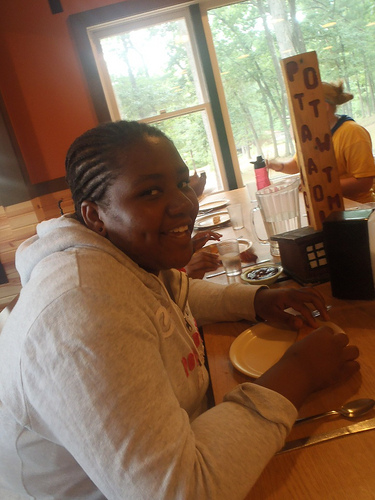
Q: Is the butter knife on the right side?
A: Yes, the butter knife is on the right of the image.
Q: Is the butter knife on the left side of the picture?
A: No, the butter knife is on the right of the image.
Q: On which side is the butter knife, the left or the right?
A: The butter knife is on the right of the image.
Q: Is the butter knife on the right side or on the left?
A: The butter knife is on the right of the image.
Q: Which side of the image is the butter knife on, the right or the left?
A: The butter knife is on the right of the image.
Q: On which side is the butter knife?
A: The butter knife is on the right of the image.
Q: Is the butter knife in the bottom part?
A: Yes, the butter knife is in the bottom of the image.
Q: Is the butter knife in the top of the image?
A: No, the butter knife is in the bottom of the image.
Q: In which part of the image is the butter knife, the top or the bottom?
A: The butter knife is in the bottom of the image.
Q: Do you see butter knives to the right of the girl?
A: Yes, there is a butter knife to the right of the girl.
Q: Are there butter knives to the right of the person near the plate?
A: Yes, there is a butter knife to the right of the girl.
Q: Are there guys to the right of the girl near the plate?
A: No, there is a butter knife to the right of the girl.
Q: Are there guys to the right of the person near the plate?
A: No, there is a butter knife to the right of the girl.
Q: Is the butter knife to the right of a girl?
A: Yes, the butter knife is to the right of a girl.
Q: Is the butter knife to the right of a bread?
A: No, the butter knife is to the right of a girl.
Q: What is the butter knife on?
A: The butter knife is on the table.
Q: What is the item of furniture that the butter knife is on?
A: The piece of furniture is a table.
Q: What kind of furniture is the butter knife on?
A: The butter knife is on the table.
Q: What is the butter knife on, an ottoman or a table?
A: The butter knife is on a table.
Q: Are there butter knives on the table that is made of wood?
A: Yes, there is a butter knife on the table.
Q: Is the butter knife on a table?
A: Yes, the butter knife is on a table.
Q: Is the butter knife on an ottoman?
A: No, the butter knife is on a table.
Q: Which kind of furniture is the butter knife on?
A: The butter knife is on the table.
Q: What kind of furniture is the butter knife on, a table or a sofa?
A: The butter knife is on a table.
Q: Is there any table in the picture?
A: Yes, there is a table.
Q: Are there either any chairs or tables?
A: Yes, there is a table.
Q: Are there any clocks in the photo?
A: No, there are no clocks.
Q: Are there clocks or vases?
A: No, there are no clocks or vases.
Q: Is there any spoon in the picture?
A: Yes, there is a spoon.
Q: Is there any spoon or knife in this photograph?
A: Yes, there is a spoon.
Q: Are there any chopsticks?
A: No, there are no chopsticks.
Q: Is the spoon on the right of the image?
A: Yes, the spoon is on the right of the image.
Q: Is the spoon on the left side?
A: No, the spoon is on the right of the image.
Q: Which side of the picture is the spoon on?
A: The spoon is on the right of the image.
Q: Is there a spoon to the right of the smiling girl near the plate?
A: Yes, there is a spoon to the right of the girl.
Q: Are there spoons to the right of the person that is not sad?
A: Yes, there is a spoon to the right of the girl.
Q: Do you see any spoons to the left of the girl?
A: No, the spoon is to the right of the girl.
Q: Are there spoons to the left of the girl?
A: No, the spoon is to the right of the girl.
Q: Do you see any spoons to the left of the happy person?
A: No, the spoon is to the right of the girl.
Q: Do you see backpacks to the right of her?
A: No, there is a spoon to the right of the girl.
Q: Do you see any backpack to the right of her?
A: No, there is a spoon to the right of the girl.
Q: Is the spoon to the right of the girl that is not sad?
A: Yes, the spoon is to the right of the girl.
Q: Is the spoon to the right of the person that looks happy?
A: Yes, the spoon is to the right of the girl.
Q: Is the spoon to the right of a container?
A: No, the spoon is to the right of the girl.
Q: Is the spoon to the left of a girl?
A: No, the spoon is to the right of a girl.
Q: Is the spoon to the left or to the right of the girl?
A: The spoon is to the right of the girl.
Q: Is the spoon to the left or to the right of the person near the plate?
A: The spoon is to the right of the girl.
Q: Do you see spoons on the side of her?
A: Yes, there is a spoon on the side of the girl.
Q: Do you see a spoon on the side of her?
A: Yes, there is a spoon on the side of the girl.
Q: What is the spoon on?
A: The spoon is on the table.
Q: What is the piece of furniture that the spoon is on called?
A: The piece of furniture is a table.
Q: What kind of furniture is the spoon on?
A: The spoon is on the table.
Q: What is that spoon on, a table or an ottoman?
A: The spoon is on a table.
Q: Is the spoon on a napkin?
A: No, the spoon is on a table.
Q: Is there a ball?
A: No, there are no balls.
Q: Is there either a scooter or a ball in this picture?
A: No, there are no balls or scooters.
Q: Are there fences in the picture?
A: No, there are no fences.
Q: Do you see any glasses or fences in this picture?
A: No, there are no fences or glasses.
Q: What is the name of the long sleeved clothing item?
A: The clothing item is a shirt.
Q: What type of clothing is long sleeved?
A: The clothing is a shirt.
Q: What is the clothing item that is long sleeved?
A: The clothing item is a shirt.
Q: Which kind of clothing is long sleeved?
A: The clothing is a shirt.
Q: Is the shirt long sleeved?
A: Yes, the shirt is long sleeved.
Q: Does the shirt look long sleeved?
A: Yes, the shirt is long sleeved.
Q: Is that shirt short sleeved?
A: No, the shirt is long sleeved.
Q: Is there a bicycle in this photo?
A: No, there are no bicycles.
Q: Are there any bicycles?
A: No, there are no bicycles.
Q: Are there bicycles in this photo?
A: No, there are no bicycles.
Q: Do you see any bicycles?
A: No, there are no bicycles.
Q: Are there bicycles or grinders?
A: No, there are no bicycles or grinders.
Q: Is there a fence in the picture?
A: No, there are no fences.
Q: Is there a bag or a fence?
A: No, there are no fences or bags.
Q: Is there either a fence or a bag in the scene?
A: No, there are no fences or bags.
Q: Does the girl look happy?
A: Yes, the girl is happy.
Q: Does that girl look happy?
A: Yes, the girl is happy.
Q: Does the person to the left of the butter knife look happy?
A: Yes, the girl is happy.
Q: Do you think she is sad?
A: No, the girl is happy.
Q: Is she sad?
A: No, the girl is happy.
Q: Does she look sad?
A: No, the girl is happy.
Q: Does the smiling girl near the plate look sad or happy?
A: The girl is happy.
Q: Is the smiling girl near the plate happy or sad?
A: The girl is happy.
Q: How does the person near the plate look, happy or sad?
A: The girl is happy.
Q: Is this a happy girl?
A: Yes, this is a happy girl.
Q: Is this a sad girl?
A: No, this is a happy girl.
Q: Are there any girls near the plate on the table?
A: Yes, there is a girl near the plate.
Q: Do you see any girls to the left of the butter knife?
A: Yes, there is a girl to the left of the butter knife.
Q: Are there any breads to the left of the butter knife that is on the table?
A: No, there is a girl to the left of the butter knife.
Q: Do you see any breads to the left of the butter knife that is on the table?
A: No, there is a girl to the left of the butter knife.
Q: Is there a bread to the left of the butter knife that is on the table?
A: No, there is a girl to the left of the butter knife.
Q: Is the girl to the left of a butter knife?
A: Yes, the girl is to the left of a butter knife.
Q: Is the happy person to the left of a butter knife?
A: Yes, the girl is to the left of a butter knife.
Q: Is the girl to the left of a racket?
A: No, the girl is to the left of a butter knife.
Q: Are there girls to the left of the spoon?
A: Yes, there is a girl to the left of the spoon.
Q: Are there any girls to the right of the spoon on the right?
A: No, the girl is to the left of the spoon.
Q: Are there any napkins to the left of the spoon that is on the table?
A: No, there is a girl to the left of the spoon.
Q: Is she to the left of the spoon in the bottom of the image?
A: Yes, the girl is to the left of the spoon.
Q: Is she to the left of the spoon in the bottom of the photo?
A: Yes, the girl is to the left of the spoon.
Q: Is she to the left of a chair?
A: No, the girl is to the left of the spoon.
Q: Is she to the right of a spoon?
A: No, the girl is to the left of a spoon.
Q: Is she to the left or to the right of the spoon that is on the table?
A: The girl is to the left of the spoon.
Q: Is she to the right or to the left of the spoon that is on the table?
A: The girl is to the left of the spoon.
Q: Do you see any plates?
A: Yes, there is a plate.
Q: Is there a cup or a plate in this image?
A: Yes, there is a plate.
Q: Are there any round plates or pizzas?
A: Yes, there is a round plate.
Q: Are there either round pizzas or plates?
A: Yes, there is a round plate.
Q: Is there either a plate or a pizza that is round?
A: Yes, the plate is round.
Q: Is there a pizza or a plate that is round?
A: Yes, the plate is round.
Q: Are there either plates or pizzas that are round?
A: Yes, the plate is round.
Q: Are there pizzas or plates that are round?
A: Yes, the plate is round.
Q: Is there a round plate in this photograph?
A: Yes, there is a round plate.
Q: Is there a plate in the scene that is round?
A: Yes, there is a plate that is round.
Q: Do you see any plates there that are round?
A: Yes, there is a plate that is round.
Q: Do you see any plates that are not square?
A: Yes, there is a round plate.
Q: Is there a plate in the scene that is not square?
A: Yes, there is a round plate.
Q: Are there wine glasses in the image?
A: No, there are no wine glasses.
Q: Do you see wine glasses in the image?
A: No, there are no wine glasses.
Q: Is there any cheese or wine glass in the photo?
A: No, there are no wine glasses or cheese.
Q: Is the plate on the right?
A: Yes, the plate is on the right of the image.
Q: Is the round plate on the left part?
A: No, the plate is on the right of the image.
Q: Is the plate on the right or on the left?
A: The plate is on the right of the image.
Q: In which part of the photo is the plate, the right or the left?
A: The plate is on the right of the image.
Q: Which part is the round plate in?
A: The plate is on the right of the image.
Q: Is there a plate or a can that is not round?
A: No, there is a plate but it is round.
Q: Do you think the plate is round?
A: Yes, the plate is round.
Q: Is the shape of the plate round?
A: Yes, the plate is round.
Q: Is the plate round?
A: Yes, the plate is round.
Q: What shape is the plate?
A: The plate is round.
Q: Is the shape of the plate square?
A: No, the plate is round.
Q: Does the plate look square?
A: No, the plate is round.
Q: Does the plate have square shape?
A: No, the plate is round.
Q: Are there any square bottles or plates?
A: No, there is a plate but it is round.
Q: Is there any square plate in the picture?
A: No, there is a plate but it is round.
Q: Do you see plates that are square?
A: No, there is a plate but it is round.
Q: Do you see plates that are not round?
A: No, there is a plate but it is round.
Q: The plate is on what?
A: The plate is on the table.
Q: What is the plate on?
A: The plate is on the table.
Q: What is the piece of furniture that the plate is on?
A: The piece of furniture is a table.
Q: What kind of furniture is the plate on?
A: The plate is on the table.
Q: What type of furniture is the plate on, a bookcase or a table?
A: The plate is on a table.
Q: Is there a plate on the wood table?
A: Yes, there is a plate on the table.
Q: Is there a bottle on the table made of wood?
A: No, there is a plate on the table.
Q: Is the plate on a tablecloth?
A: No, the plate is on the table.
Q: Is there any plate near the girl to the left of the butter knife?
A: Yes, there is a plate near the girl.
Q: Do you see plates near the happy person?
A: Yes, there is a plate near the girl.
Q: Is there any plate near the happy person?
A: Yes, there is a plate near the girl.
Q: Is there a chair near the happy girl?
A: No, there is a plate near the girl.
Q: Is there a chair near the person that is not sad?
A: No, there is a plate near the girl.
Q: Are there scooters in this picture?
A: No, there are no scooters.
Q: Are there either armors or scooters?
A: No, there are no scooters or armors.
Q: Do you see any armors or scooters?
A: No, there are no scooters or armors.